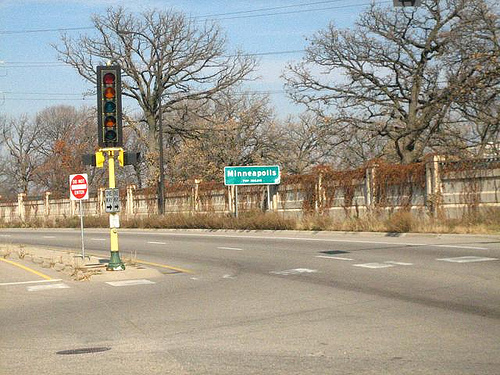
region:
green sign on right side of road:
[216, 154, 288, 221]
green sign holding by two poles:
[216, 158, 285, 223]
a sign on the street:
[66, 170, 97, 263]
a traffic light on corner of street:
[93, 63, 134, 273]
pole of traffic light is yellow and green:
[96, 146, 134, 273]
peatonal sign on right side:
[113, 142, 148, 172]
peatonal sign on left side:
[78, 141, 109, 173]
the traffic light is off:
[93, 60, 129, 152]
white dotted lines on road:
[125, 232, 356, 268]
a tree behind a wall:
[290, 13, 499, 214]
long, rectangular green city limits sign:
[222, 165, 278, 185]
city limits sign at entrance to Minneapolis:
[223, 166, 281, 185]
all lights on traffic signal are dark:
[97, 63, 122, 148]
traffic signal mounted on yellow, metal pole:
[80, 65, 141, 270]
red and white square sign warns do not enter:
[70, 171, 90, 201]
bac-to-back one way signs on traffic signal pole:
[102, 188, 122, 214]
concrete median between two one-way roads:
[0, 241, 162, 282]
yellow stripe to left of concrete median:
[0, 256, 48, 277]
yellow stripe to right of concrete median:
[75, 250, 190, 275]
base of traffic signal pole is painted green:
[105, 250, 124, 272]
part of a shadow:
[92, 340, 101, 355]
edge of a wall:
[344, 163, 355, 180]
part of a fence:
[329, 196, 334, 207]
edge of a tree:
[387, 125, 406, 144]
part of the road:
[310, 255, 320, 306]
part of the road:
[65, 201, 80, 217]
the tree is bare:
[128, 43, 198, 147]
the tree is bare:
[170, 43, 241, 128]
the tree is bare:
[328, 46, 402, 134]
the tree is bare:
[105, 55, 216, 111]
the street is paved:
[88, 223, 232, 310]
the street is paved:
[173, 223, 355, 333]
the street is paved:
[145, 211, 302, 356]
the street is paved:
[185, 323, 258, 373]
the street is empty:
[140, 205, 358, 312]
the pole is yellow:
[95, 148, 140, 269]